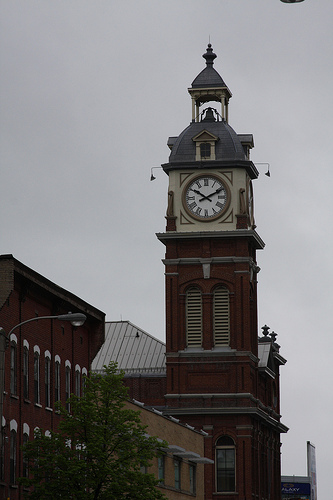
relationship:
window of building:
[189, 452, 202, 495] [1, 29, 317, 494]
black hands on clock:
[191, 180, 220, 200] [176, 177, 237, 221]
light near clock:
[7, 308, 92, 332] [171, 170, 235, 225]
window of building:
[226, 448, 236, 470] [192, 397, 269, 451]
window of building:
[182, 106, 254, 172] [154, 58, 298, 494]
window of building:
[189, 465, 196, 496] [83, 380, 210, 495]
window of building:
[39, 345, 56, 412] [0, 252, 108, 496]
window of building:
[43, 355, 50, 407] [0, 252, 108, 496]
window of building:
[215, 445, 239, 492] [122, 34, 301, 478]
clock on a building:
[169, 169, 243, 226] [1, 30, 286, 499]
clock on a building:
[181, 172, 232, 224] [1, 30, 286, 499]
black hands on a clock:
[199, 188, 222, 201] [181, 171, 230, 218]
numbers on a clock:
[199, 177, 220, 190] [181, 165, 235, 212]